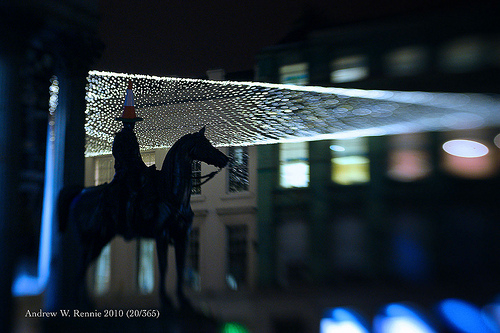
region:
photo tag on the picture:
[16, 302, 168, 323]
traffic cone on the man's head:
[116, 75, 138, 120]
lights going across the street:
[95, 62, 392, 143]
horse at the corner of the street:
[31, 126, 222, 314]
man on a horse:
[117, 107, 185, 208]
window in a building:
[211, 212, 251, 288]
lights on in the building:
[277, 137, 375, 188]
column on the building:
[37, 30, 92, 245]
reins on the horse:
[188, 165, 225, 195]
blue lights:
[319, 300, 496, 327]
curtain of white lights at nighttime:
[86, 70, 410, 143]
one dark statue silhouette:
[46, 105, 236, 320]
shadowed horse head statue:
[160, 125, 230, 192]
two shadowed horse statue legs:
[151, 242, 193, 317]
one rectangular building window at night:
[213, 204, 258, 304]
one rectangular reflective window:
[222, 143, 254, 204]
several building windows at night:
[274, 131, 496, 194]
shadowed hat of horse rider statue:
[113, 103, 145, 125]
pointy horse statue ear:
[193, 121, 210, 133]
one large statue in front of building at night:
[51, 105, 256, 313]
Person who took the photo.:
[24, 300, 104, 323]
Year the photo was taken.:
[102, 304, 126, 321]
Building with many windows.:
[257, 130, 435, 295]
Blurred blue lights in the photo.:
[335, 293, 479, 330]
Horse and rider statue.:
[50, 110, 232, 298]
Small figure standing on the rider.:
[118, 78, 145, 119]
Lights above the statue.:
[49, 64, 259, 149]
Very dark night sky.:
[96, 18, 253, 51]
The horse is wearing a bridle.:
[158, 119, 233, 206]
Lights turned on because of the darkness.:
[267, 128, 419, 189]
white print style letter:
[25, 306, 33, 318]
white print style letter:
[29, 309, 36, 318]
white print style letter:
[35, 308, 42, 319]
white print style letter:
[43, 309, 51, 319]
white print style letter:
[48, 309, 57, 316]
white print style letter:
[60, 309, 70, 317]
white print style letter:
[71, 306, 80, 317]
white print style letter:
[78, 311, 85, 317]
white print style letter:
[83, 311, 88, 318]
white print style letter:
[88, 310, 94, 317]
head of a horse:
[177, 122, 236, 177]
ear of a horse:
[198, 122, 208, 136]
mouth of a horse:
[217, 150, 237, 174]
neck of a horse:
[149, 150, 194, 171]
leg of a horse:
[173, 232, 196, 302]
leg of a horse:
[146, 225, 176, 317]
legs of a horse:
[45, 230, 105, 310]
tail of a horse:
[40, 176, 70, 248]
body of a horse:
[86, 180, 173, 244]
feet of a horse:
[158, 291, 200, 316]